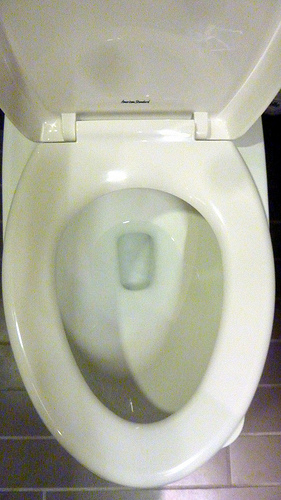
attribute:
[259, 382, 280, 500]
floor — tiled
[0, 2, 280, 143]
seat lid — raised 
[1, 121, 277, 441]
seat — down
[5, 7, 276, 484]
bathroom — white porcelain, beige, clean  , white 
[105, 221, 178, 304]
water — clear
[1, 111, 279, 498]
floor — tile 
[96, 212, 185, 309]
water — Clear 